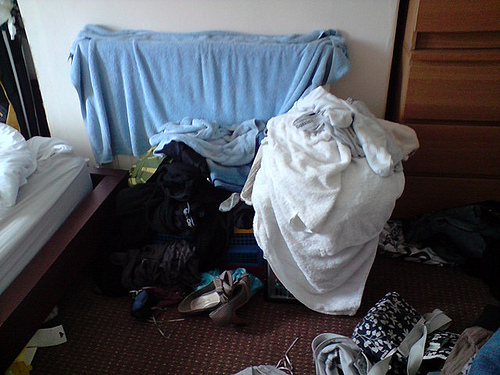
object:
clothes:
[235, 204, 499, 375]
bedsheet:
[0, 136, 91, 295]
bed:
[0, 120, 126, 374]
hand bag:
[352, 292, 460, 367]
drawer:
[415, 0, 498, 50]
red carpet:
[0, 181, 500, 375]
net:
[0, 122, 74, 212]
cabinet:
[402, 1, 498, 238]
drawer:
[403, 50, 498, 125]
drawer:
[399, 122, 498, 179]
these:
[109, 154, 262, 318]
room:
[0, 0, 500, 375]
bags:
[91, 140, 225, 290]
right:
[370, 74, 397, 122]